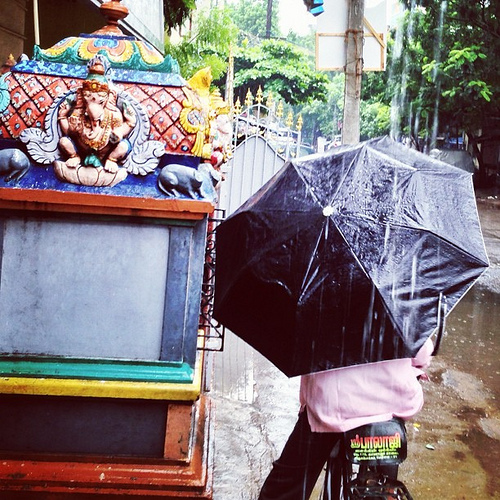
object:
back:
[344, 419, 408, 467]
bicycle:
[319, 415, 412, 500]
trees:
[163, 0, 498, 187]